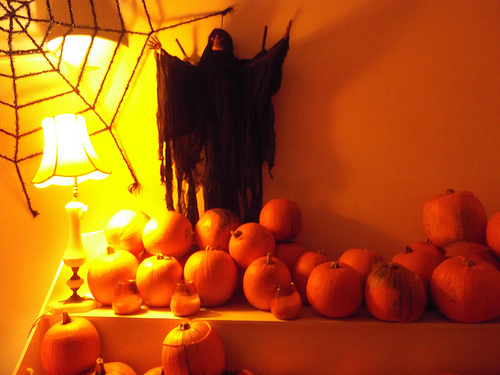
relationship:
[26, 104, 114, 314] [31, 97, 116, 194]
lamp has shade